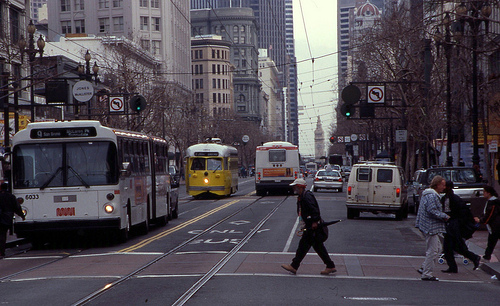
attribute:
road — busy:
[9, 161, 498, 304]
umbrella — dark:
[293, 213, 344, 237]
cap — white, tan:
[287, 176, 309, 189]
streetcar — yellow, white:
[182, 136, 241, 199]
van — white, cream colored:
[340, 156, 412, 219]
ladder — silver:
[352, 158, 373, 216]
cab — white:
[309, 161, 346, 194]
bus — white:
[8, 118, 197, 257]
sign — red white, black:
[364, 84, 389, 105]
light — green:
[343, 103, 355, 120]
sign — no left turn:
[106, 96, 130, 112]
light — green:
[131, 95, 148, 116]